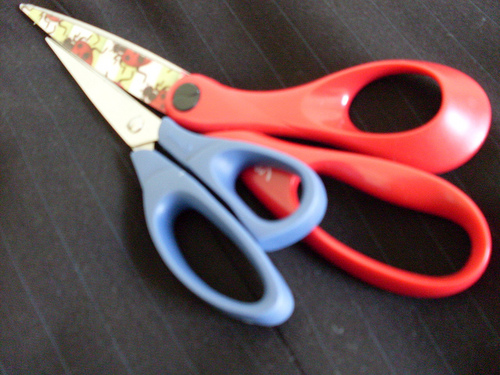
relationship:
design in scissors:
[36, 1, 174, 95] [19, 0, 491, 327]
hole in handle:
[209, 155, 322, 238] [124, 103, 340, 335]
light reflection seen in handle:
[443, 102, 488, 149] [190, 57, 490, 299]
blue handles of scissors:
[126, 115, 331, 332] [19, 0, 491, 327]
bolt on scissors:
[124, 115, 147, 134] [39, 28, 331, 334]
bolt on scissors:
[123, 107, 153, 141] [19, 0, 491, 327]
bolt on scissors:
[161, 80, 201, 111] [39, 28, 331, 334]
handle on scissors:
[190, 57, 490, 299] [19, 0, 491, 327]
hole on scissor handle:
[296, 175, 477, 277] [192, 125, 497, 300]